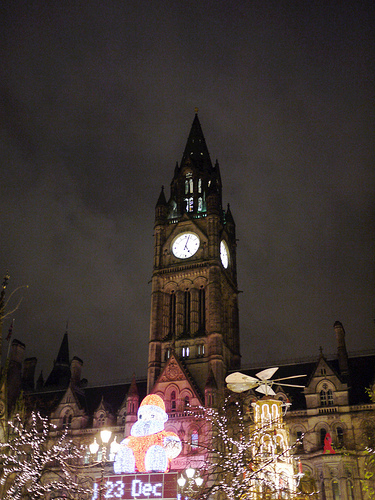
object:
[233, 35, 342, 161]
night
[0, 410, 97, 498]
lights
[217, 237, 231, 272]
clock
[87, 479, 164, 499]
date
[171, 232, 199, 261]
clock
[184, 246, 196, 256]
5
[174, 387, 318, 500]
lights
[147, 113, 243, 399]
building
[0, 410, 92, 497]
tree